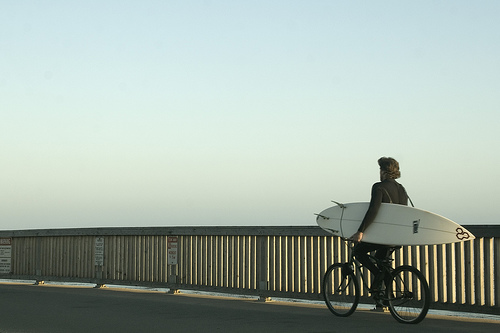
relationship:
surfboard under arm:
[316, 202, 476, 244] [358, 183, 383, 233]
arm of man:
[358, 183, 383, 233] [349, 157, 408, 309]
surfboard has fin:
[316, 202, 476, 244] [332, 200, 348, 210]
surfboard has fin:
[316, 202, 476, 244] [313, 212, 329, 221]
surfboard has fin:
[316, 202, 476, 244] [326, 227, 340, 235]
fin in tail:
[332, 200, 348, 210] [316, 202, 346, 240]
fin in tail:
[313, 212, 329, 221] [316, 202, 346, 240]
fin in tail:
[326, 227, 340, 235] [316, 202, 346, 240]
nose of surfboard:
[456, 221, 476, 246] [316, 202, 476, 244]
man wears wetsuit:
[349, 157, 408, 309] [351, 181, 409, 296]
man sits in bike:
[349, 157, 408, 309] [322, 240, 432, 324]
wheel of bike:
[322, 262, 360, 317] [322, 240, 432, 324]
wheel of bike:
[385, 266, 431, 325] [322, 240, 432, 324]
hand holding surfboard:
[349, 231, 362, 245] [316, 202, 476, 244]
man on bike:
[349, 157, 408, 309] [322, 240, 432, 324]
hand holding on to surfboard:
[349, 231, 362, 245] [316, 202, 476, 244]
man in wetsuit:
[349, 157, 408, 309] [351, 181, 409, 296]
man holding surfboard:
[349, 157, 408, 309] [316, 202, 476, 244]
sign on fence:
[165, 235, 180, 266] [0, 225, 499, 316]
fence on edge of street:
[0, 225, 499, 316] [1, 291, 500, 332]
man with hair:
[349, 157, 408, 309] [378, 157, 401, 182]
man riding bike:
[349, 157, 408, 309] [322, 240, 432, 324]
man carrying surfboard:
[349, 157, 408, 309] [316, 202, 476, 244]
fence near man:
[0, 225, 499, 316] [349, 157, 408, 309]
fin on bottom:
[332, 200, 348, 210] [316, 202, 476, 246]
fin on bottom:
[313, 212, 329, 221] [316, 202, 476, 246]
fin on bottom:
[326, 227, 340, 235] [316, 202, 476, 246]